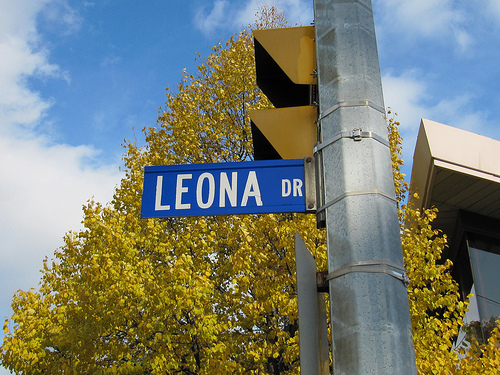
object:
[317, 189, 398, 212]
ring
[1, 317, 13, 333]
leaf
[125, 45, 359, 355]
tree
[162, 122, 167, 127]
leaf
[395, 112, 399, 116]
leaf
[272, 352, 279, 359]
leaf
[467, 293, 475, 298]
leaf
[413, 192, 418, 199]
leaf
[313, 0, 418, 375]
metal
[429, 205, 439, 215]
leaf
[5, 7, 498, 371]
yellow leaves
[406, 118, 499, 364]
building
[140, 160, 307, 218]
sign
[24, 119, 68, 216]
clouds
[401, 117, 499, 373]
tan building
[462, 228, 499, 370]
windows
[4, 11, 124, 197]
cloud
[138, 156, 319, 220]
street sign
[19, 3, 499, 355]
tree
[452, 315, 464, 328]
yellow leaf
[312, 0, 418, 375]
pole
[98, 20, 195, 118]
sky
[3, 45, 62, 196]
clouds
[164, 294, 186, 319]
leaf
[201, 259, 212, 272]
leaf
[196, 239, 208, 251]
leaf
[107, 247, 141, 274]
leaf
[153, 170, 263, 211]
white letters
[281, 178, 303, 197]
white letters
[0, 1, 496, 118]
sky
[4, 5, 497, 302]
sky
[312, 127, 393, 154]
band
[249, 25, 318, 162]
crossing signal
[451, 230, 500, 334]
window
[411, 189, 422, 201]
leaf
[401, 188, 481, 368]
tree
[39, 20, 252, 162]
sky